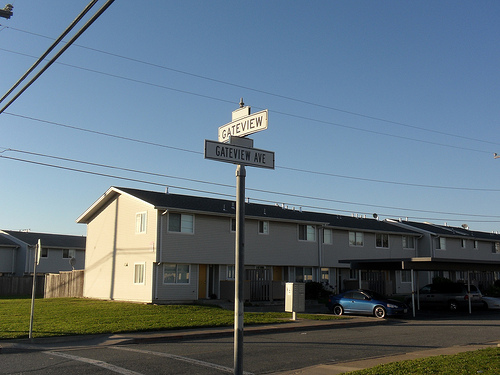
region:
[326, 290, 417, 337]
The car is small and blue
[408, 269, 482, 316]
The van is big and brown.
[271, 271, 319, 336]
The mail box is where you receive your mail.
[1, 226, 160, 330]
The grass is healthy and green.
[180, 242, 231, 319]
This door is bright yellow.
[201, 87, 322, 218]
The sign says gateway ave.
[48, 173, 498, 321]
This is a very nice big house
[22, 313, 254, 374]
The stripes on the road are white.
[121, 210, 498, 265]
There is about 12 windows.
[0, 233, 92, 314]
This fence is old and wooden.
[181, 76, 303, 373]
A pair of white street signs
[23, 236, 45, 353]
The back of a stop sign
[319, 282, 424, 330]
A blue car parked in the driveway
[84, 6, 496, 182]
The clear, blue sky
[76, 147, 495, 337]
Houses on the side of the road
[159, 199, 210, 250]
A window on the side of the house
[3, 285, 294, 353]
Grass on the front lawn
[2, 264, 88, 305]
A wooden fence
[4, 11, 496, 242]
Electrical wires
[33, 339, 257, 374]
White street lines on the road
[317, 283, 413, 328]
car parked near a curb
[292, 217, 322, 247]
window on a building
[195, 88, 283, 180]
street sign on a pole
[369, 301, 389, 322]
front wheel on a vehicle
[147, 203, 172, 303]
rain gutter on a building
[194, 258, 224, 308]
door on a building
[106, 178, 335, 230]
black roof on a building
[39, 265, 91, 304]
fence near a building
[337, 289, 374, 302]
side window on a vehicle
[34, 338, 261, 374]
white crosswalk stripes on a street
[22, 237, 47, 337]
traffic sign on pole.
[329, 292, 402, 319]
blue vehicle near building.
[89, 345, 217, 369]
white lines on the road.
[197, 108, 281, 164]
white street signs on pole.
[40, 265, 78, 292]
wooden fence in the yard.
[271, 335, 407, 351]
shadows on the street.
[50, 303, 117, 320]
green grass on the lawn.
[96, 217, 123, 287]
tan siding on building.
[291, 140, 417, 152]
blue skies above building.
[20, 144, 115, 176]
electrical wires in the air.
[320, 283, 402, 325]
a car parked in front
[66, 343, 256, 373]
white lines on the crosswalk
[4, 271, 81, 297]
a wooden fence behind the building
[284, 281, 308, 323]
a mailbox on the front lawn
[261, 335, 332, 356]
black pavement on the street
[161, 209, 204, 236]
windows in the building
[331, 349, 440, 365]
a sidewalk on the side of the road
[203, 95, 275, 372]
a street sign across the street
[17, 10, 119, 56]
electrical wires handing above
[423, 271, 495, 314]
cars parked under a canopy